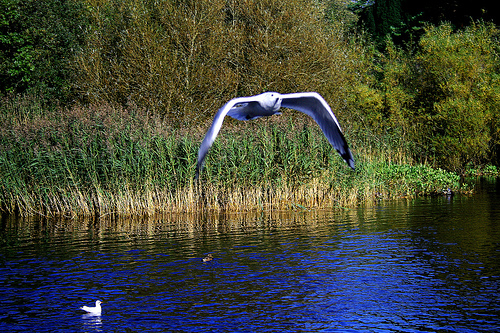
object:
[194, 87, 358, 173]
bird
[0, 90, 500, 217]
grass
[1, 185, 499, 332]
water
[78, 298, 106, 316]
bird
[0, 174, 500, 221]
shoreline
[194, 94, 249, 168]
wing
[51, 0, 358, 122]
tree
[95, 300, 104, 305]
beak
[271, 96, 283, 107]
beak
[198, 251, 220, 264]
birds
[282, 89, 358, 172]
wing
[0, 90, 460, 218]
brush